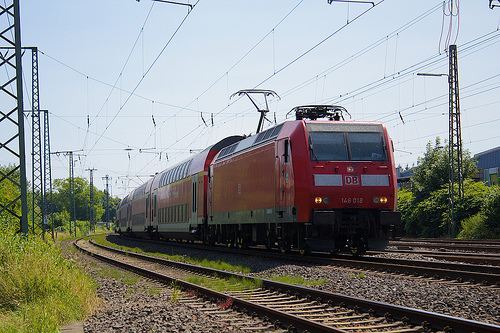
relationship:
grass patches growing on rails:
[117, 242, 267, 302] [97, 239, 276, 330]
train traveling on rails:
[104, 97, 406, 263] [69, 230, 499, 330]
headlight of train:
[313, 194, 330, 204] [104, 97, 406, 263]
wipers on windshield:
[306, 135, 392, 165] [306, 123, 384, 163]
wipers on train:
[306, 135, 392, 165] [83, 87, 406, 267]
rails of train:
[97, 239, 276, 330] [104, 97, 406, 263]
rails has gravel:
[97, 239, 276, 330] [321, 262, 449, 302]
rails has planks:
[49, 221, 499, 331] [234, 284, 369, 321]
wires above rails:
[2, 3, 499, 119] [69, 230, 499, 330]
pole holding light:
[438, 38, 482, 175] [415, 64, 455, 93]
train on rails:
[104, 97, 406, 263] [97, 239, 276, 330]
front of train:
[286, 114, 404, 241] [100, 113, 406, 267]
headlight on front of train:
[311, 194, 330, 210] [104, 97, 406, 263]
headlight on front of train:
[373, 192, 397, 215] [94, 104, 414, 273]